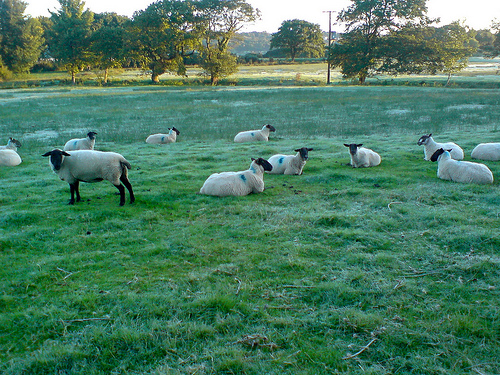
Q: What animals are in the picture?
A: Sheep.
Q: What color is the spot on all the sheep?
A: Blue.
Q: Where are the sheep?
A: In a field.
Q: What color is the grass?
A: Green.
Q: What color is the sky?
A: White.